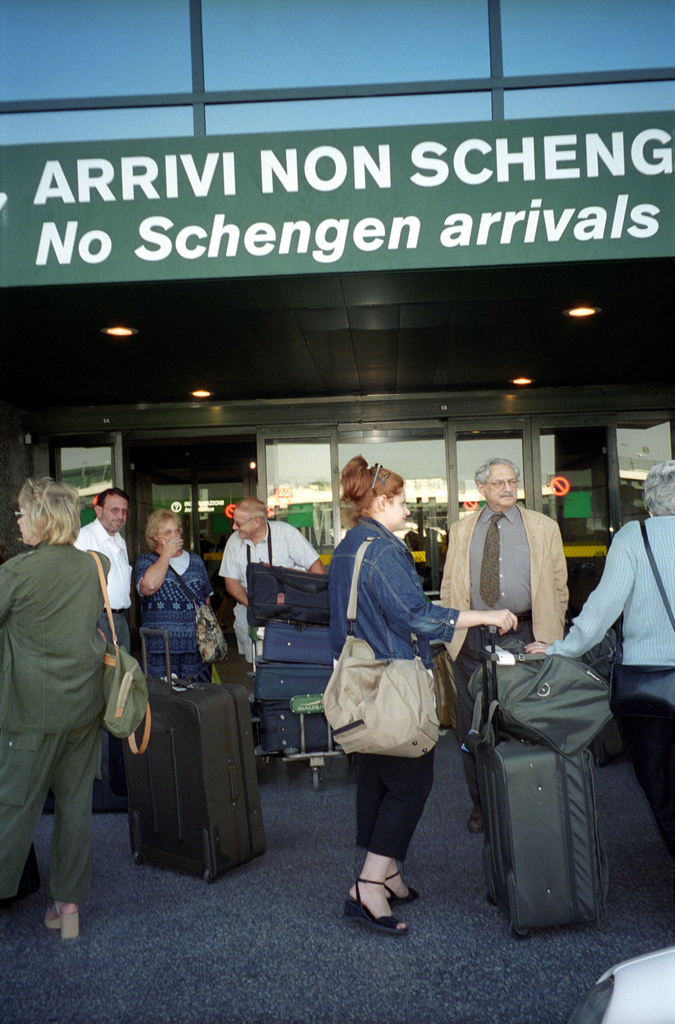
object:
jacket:
[439, 506, 571, 660]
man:
[439, 458, 570, 828]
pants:
[0, 707, 93, 909]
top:
[14, 545, 111, 726]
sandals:
[346, 871, 420, 936]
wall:
[0, 365, 46, 540]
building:
[0, 6, 675, 641]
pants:
[355, 751, 436, 860]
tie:
[479, 509, 502, 607]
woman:
[523, 468, 675, 863]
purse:
[609, 517, 674, 734]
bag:
[87, 547, 152, 758]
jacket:
[0, 536, 115, 727]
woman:
[0, 473, 108, 936]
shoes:
[43, 903, 82, 942]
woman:
[322, 455, 519, 932]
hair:
[340, 455, 404, 520]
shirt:
[74, 514, 134, 610]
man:
[74, 485, 132, 799]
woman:
[137, 507, 228, 687]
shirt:
[137, 551, 210, 616]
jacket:
[325, 517, 461, 686]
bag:
[320, 529, 439, 770]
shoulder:
[333, 525, 395, 593]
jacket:
[546, 517, 674, 671]